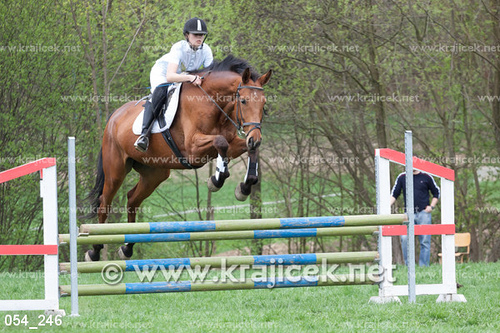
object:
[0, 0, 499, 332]
field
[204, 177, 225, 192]
shoes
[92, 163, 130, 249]
hind legs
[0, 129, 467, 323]
fencing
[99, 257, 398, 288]
text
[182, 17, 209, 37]
helmet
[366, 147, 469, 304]
gate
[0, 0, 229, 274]
trees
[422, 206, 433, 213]
hand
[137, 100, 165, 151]
boots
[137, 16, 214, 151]
female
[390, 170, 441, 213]
shirt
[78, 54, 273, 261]
horse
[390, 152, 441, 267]
man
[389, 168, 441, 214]
top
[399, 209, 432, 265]
jeans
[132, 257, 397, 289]
website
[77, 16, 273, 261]
jump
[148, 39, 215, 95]
clothes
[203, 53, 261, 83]
hair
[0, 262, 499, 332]
grass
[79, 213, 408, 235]
pole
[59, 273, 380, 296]
pole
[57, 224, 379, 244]
pole